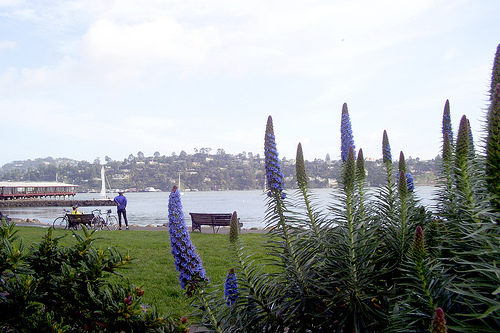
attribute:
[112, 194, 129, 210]
shirt — long-sleeved, purple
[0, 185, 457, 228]
water — body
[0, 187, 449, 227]
body — water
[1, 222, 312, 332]
grass — patch